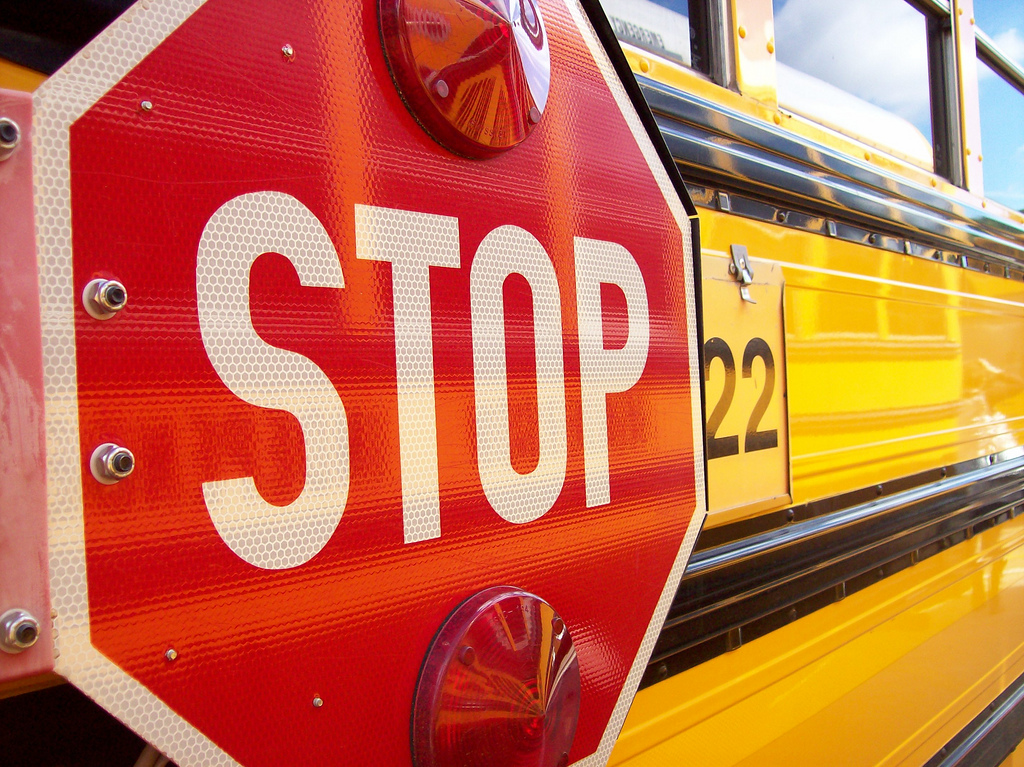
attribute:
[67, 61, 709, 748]
sign — white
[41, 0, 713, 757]
stop sign — red, school bus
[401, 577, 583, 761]
reflector — red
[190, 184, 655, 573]
lettering — white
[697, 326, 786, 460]
number 22 — black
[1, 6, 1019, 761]
bus — one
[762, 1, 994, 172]
windows — black, tinted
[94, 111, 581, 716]
sign — stop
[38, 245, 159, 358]
screws — large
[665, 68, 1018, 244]
paneling — black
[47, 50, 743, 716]
sign — white, red, stop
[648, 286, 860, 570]
number — identification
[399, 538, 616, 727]
light — warning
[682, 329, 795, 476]
number — attached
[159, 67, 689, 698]
sign — attached, stop, white, red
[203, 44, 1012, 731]
bus — school, yellow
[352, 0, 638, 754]
reflectors — red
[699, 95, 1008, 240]
stripe — black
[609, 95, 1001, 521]
vehicle — reflected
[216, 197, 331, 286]
pattern — circular, reflective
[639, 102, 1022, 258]
siding — black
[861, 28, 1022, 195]
sky — reflected, blue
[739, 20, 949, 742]
bus — yellow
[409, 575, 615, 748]
light — red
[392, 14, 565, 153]
light — red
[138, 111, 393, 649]
surface — bumpy, reflective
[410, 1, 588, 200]
light — red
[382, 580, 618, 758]
light — red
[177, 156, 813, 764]
sign — red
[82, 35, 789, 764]
sign — red, white, octagonal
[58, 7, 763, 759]
sign — stop, red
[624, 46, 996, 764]
bus — yellow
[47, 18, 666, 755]
sign — stop, reflective, red, white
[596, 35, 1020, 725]
bus — yellow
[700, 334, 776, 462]
number 22 — black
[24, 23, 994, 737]
school bus — yellow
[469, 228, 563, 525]
letter o — white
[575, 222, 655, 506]
letter p — white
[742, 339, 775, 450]
number 2 — black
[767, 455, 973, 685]
paint — yellow and black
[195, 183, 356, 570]
letter s — white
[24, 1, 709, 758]
sign — stop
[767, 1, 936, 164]
bus window — school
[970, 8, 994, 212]
bus window — school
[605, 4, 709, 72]
bus window — school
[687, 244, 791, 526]
background — yellow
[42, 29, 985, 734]
bus — school, yellow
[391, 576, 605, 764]
light — red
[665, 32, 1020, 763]
bus — yellow 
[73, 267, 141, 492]
bolts — double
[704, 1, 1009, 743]
bus — one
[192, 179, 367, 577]
letter — large 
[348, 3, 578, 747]
lights — red, flashing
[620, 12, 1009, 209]
windows — some, sliding , bus 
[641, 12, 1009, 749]
bus — yellow, one, black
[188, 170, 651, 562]
word — one, white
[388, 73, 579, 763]
lights — red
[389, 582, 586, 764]
reflector — red, safety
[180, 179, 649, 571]
letters — white , reflective , block 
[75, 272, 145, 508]
bolts — metal